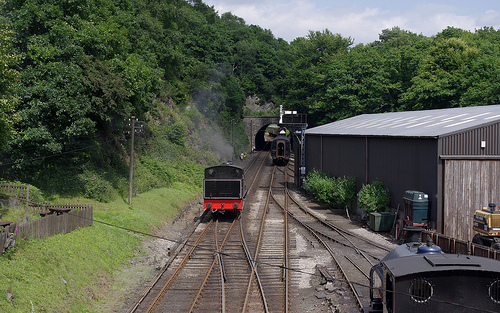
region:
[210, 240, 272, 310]
train tracks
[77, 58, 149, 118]
a green bush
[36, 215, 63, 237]
a fence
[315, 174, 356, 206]
the green plants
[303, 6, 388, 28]
clouds in the sky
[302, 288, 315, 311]
dirt on the tracks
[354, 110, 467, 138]
roof of the building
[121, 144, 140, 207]
a pole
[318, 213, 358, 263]
the train tracks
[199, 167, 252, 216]
a train in on the tracks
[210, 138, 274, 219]
black and red train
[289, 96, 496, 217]
grey building near train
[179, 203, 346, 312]
train on brown tracks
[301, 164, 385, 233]
green bushes near building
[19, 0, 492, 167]
tall green trees in background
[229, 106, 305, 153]
tracks lead under tunnel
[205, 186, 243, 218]
red stripe on train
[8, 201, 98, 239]
brown fence on hill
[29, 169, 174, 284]
green grass on hill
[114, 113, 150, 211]
telephone pole left of train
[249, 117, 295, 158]
Train heading for the tunnel.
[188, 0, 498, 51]
Cloudy sky with some blue.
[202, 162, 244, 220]
Red and black train car.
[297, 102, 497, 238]
Metal building with roof having some yellow stripes.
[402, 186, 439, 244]
Blue garbage can on side of a building.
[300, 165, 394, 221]
Three green bushes on side of building.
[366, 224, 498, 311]
Black and dark green train engine with smokestack.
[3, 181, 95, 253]
Two brown wooden fences on ground..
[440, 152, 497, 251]
Sliding door on side of a building.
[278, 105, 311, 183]
Tower next to train tracks.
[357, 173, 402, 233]
Green bush on side of building.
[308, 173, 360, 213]
Green bush on side of building.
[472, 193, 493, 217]
Yellow tractor near building.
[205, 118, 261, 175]
Smoke coming from top of train.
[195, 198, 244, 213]
Bottom section of train is red.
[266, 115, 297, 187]
Brown door on back of train.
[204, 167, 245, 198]
Top section of train is black.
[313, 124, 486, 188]
Large brown building near tracks.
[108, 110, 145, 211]
Wood pole near train tracks.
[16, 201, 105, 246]
Wood fence next to tracks.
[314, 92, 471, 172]
the roof is gray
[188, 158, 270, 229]
a black train car